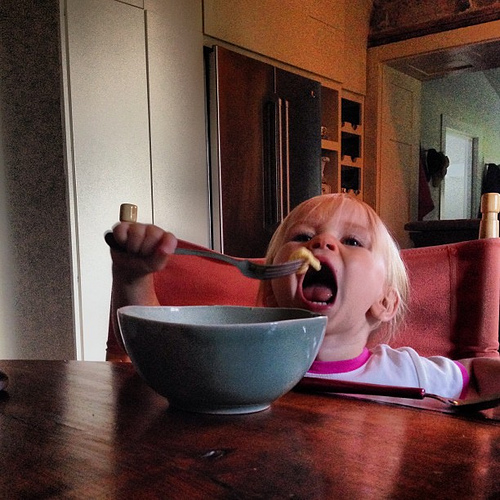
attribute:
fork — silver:
[172, 238, 307, 278]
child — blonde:
[213, 181, 494, 408]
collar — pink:
[305, 344, 375, 375]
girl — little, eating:
[108, 194, 497, 400]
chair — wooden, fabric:
[106, 192, 498, 366]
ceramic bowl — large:
[113, 302, 332, 419]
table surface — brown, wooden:
[7, 410, 489, 497]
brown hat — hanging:
[422, 145, 449, 191]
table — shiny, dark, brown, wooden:
[286, 417, 486, 469]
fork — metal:
[97, 215, 421, 344]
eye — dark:
[341, 236, 363, 246]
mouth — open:
[296, 252, 338, 315]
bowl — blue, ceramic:
[115, 304, 327, 415]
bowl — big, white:
[113, 302, 330, 423]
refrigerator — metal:
[199, 34, 338, 279]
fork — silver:
[139, 224, 319, 300]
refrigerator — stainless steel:
[231, 71, 299, 214]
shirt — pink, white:
[313, 345, 465, 409]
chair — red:
[118, 214, 496, 424]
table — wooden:
[6, 354, 498, 484]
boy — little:
[92, 180, 499, 409]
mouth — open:
[295, 256, 342, 310]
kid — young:
[92, 189, 499, 427]